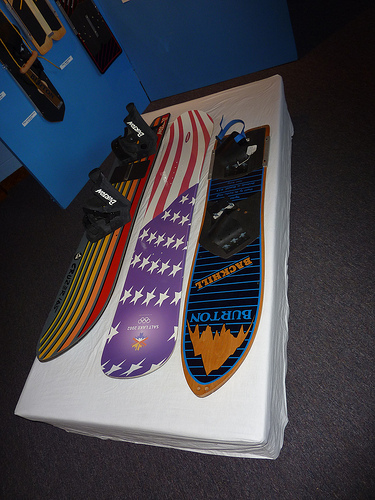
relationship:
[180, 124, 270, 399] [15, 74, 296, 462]
snowboard on table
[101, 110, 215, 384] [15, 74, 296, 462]
snowboard on table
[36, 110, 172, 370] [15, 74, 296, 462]
snowboard on table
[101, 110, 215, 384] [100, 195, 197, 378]
snowboard with stars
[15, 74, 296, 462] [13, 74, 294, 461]
table has cloth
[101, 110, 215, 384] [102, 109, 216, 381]
snowboard has flag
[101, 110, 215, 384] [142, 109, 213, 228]
snowboard has stripes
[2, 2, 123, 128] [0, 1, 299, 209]
snowboards on wall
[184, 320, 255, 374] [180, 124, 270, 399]
decal on snowboard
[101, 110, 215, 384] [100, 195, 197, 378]
snowboard has stars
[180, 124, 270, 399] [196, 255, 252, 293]
snowboard has word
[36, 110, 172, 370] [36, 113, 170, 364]
snowboard has lines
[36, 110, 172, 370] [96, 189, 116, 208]
snowboard has word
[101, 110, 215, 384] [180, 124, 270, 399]
snowboard beside snowboard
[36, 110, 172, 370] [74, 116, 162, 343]
snowboard has stripe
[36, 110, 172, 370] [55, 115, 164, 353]
snowboard has stripe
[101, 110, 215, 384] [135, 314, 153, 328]
snowboard has symbol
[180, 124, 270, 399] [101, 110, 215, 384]
snowboard near snowboard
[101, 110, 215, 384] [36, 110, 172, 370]
snowboard near snowboard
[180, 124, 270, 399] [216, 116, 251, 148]
snowboard has footstrap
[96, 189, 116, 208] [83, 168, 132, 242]
word on black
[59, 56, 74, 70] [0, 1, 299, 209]
sign on wall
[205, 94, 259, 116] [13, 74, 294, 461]
wrinkles in cloth